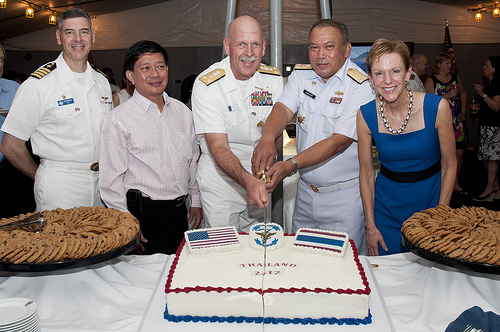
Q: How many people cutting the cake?
A: Two.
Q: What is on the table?
A: Cake and cookies.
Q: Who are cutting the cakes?
A: The captains.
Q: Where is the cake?
A: On the table.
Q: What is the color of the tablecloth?
A: White.